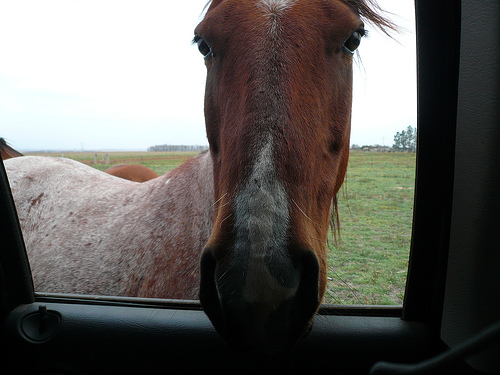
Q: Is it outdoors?
A: Yes, it is outdoors.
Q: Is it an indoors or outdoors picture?
A: It is outdoors.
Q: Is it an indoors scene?
A: No, it is outdoors.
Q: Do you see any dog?
A: No, there are no dogs.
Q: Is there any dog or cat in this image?
A: No, there are no dogs or cats.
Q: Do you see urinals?
A: No, there are no urinals.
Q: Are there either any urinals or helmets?
A: No, there are no urinals or helmets.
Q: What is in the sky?
A: The clouds are in the sky.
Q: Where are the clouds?
A: The clouds are in the sky.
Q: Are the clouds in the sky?
A: Yes, the clouds are in the sky.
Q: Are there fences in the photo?
A: No, there are no fences.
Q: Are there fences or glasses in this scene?
A: No, there are no fences or glasses.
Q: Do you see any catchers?
A: No, there are no catchers.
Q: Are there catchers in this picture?
A: No, there are no catchers.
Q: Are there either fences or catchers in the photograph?
A: No, there are no catchers or fences.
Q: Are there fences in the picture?
A: No, there are no fences.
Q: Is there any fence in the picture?
A: No, there are no fences.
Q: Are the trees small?
A: Yes, the trees are small.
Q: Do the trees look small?
A: Yes, the trees are small.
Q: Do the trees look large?
A: No, the trees are small.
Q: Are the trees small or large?
A: The trees are small.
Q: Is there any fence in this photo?
A: No, there are no fences.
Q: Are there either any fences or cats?
A: No, there are no fences or cats.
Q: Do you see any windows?
A: Yes, there is a window.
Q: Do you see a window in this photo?
A: Yes, there is a window.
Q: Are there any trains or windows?
A: Yes, there is a window.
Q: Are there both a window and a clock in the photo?
A: No, there is a window but no clocks.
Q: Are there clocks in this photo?
A: No, there are no clocks.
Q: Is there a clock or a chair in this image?
A: No, there are no clocks or chairs.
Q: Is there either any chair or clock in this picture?
A: No, there are no clocks or chairs.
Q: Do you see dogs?
A: No, there are no dogs.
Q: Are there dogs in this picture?
A: No, there are no dogs.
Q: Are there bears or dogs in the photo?
A: No, there are no dogs or bears.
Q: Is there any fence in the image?
A: No, there are no fences.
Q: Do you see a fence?
A: No, there are no fences.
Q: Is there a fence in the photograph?
A: No, there are no fences.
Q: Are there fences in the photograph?
A: No, there are no fences.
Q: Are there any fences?
A: No, there are no fences.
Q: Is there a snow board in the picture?
A: No, there are no snowboards.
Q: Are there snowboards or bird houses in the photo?
A: No, there are no snowboards or bird houses.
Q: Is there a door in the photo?
A: Yes, there is a door.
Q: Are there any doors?
A: Yes, there is a door.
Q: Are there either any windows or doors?
A: Yes, there is a door.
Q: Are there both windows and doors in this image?
A: Yes, there are both a door and windows.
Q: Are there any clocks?
A: No, there are no clocks.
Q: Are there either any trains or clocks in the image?
A: No, there are no clocks or trains.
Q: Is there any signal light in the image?
A: No, there are no traffic lights.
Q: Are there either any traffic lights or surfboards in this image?
A: No, there are no traffic lights or surfboards.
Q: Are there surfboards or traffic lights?
A: No, there are no traffic lights or surfboards.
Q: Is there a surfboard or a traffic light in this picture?
A: No, there are no traffic lights or surfboards.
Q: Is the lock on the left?
A: Yes, the lock is on the left of the image.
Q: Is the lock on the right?
A: No, the lock is on the left of the image.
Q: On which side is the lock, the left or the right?
A: The lock is on the left of the image.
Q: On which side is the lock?
A: The lock is on the left of the image.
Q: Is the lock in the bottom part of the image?
A: Yes, the lock is in the bottom of the image.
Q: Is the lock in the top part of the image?
A: No, the lock is in the bottom of the image.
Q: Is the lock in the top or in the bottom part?
A: The lock is in the bottom of the image.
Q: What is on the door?
A: The lock is on the door.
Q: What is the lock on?
A: The lock is on the door.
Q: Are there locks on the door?
A: Yes, there is a lock on the door.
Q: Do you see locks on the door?
A: Yes, there is a lock on the door.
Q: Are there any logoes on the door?
A: No, there is a lock on the door.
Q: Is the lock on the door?
A: Yes, the lock is on the door.